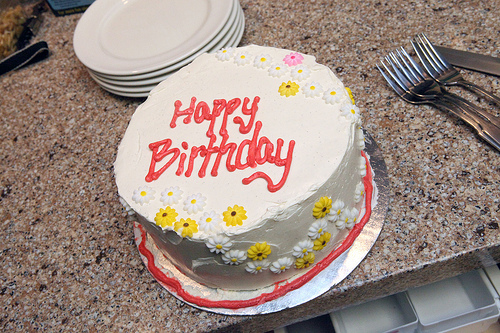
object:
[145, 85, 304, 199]
frosting that spells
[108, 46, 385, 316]
white frosted cake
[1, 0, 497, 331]
granite countertop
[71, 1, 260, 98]
white plates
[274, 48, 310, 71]
pink flower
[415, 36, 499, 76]
knife on countertop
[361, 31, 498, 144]
four forks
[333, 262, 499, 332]
storage containers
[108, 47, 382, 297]
birthday cake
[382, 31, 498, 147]
knife and forks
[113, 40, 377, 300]
white birthday cake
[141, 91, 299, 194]
red lettering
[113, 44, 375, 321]
candy decorations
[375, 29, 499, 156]
silver forks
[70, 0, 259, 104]
five white plates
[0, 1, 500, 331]
beige granite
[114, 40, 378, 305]
yellow and white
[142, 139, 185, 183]
red icing b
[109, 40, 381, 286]
"pink candy daisy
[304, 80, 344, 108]
two white daisy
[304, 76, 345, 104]
two white daisy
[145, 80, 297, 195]
letters in red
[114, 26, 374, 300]
flowers on cake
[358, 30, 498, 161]
forks on countertop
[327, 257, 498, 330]
open drawer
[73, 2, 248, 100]
"plates stacked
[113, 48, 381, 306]
uncut birthday cake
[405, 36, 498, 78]
knife behind forks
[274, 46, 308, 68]
flower on cake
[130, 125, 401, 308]
reflective tin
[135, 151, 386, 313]
around cake base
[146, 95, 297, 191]
cake has words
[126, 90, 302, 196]
happy birthday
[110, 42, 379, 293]
cake is decorated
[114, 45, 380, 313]
multiple colors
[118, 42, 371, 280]
tiny flowers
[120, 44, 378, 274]
colored flowers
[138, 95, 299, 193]
cake are red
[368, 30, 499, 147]
forks are silver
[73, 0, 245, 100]
picture has plates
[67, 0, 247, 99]
white plates in it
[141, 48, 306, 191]
on a birthday cake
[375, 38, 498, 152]
several forks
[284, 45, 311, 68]
pink daisy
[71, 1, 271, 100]
stack of plates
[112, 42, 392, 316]
cake tray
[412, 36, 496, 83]
knife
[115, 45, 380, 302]
frosting on a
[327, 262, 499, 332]
white storage bins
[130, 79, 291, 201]
frosting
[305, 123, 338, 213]
frosting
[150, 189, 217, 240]
flower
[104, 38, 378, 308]
cake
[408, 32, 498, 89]
knife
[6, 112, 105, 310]
countertop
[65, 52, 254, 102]
plates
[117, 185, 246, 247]
candy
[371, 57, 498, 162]
fork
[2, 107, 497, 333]
countertop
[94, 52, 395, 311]
cake